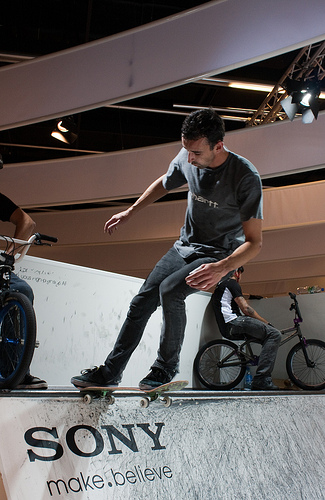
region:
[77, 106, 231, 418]
Getting ready skateboard trick.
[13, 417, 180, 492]
Sony advertisement concrete ramp.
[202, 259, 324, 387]
Boy resting bicycle corner.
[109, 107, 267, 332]
Rider leaning ramp drop off.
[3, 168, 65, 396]
Bicycle rider sits to watch.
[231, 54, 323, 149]
Overhead lighting built in.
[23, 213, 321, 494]
Indoor skateboard park ramp.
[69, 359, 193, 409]
Two feet on four wheels.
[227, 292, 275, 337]
Cyclist right arm tattooed.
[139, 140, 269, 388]
Rider all blue clothing.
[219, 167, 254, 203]
Man wearing grey shirt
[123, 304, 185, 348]
Man wearing blue jeans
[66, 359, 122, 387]
Man wearing blue sneakers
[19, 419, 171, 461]
Big black lettering on wall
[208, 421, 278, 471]
Black pencil scribbled on wall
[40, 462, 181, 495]
Small black lettering on wall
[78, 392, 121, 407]
Wheels under left side of board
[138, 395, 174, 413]
Wheels under right side of board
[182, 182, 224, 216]
White lettering on shirt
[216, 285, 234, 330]
Man wearing black and white shirt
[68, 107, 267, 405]
the man on a skateboard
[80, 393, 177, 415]
the wheels on the skateboard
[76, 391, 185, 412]
the wheels are white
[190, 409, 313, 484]
the scuff marks on the ramp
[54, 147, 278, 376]
the man wearing a t shirt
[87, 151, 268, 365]
the man wearing jeans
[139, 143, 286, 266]
the t shirt is gray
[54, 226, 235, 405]
the jeans are gray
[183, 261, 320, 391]
the man sitting on the bicycle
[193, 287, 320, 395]
the bicycle is gray and black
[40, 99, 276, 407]
dude skates dangerously above a ledge whereupon 'sony' insists he 'make.believe'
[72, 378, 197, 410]
board is pinky-brown, uptipped, w/ pinkish white wheels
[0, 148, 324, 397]
two people on bicycles either side of skater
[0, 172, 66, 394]
one person on bicycle may -not- be ignoring skater. hard to say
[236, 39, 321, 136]
due to lighting, top right, this may be being filmed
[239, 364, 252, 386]
bottled water in cemenet corner, maybe aquafina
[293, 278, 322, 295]
blue capped, green labeled, bottled water on ledge, maybe volvic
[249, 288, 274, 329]
guy in far corner ignoring 'boarder wears black wristbands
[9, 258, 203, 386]
lots of kick+grab marks on white wall below blurry words of graffiti [likely not in english]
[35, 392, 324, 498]
lots of wheel scars down front white wall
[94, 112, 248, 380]
man doing trick on skateboard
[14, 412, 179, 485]
black sign on skateboard ramp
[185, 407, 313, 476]
black and tan skateboard ramp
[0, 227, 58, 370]
bike near ramp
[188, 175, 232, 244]
man wearing black and white shirt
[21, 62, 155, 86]
white ceiling support above ramp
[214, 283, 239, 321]
young man wearing black and white shirt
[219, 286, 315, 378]
young man sitting on bike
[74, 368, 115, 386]
young man wearing green shoe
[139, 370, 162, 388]
young man wearing green shoe